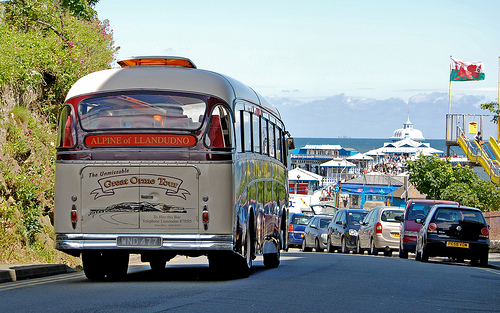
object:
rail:
[445, 113, 499, 144]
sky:
[94, 3, 498, 143]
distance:
[3, 4, 499, 166]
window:
[78, 95, 207, 130]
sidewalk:
[484, 237, 500, 270]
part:
[480, 248, 489, 267]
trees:
[5, 4, 110, 70]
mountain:
[269, 92, 491, 145]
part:
[296, 98, 369, 135]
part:
[382, 210, 403, 223]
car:
[286, 213, 315, 253]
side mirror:
[394, 216, 401, 221]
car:
[415, 204, 490, 266]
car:
[301, 215, 334, 253]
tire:
[209, 215, 253, 278]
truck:
[394, 199, 460, 259]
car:
[356, 206, 407, 255]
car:
[326, 209, 372, 253]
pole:
[447, 54, 453, 141]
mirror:
[287, 138, 295, 150]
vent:
[114, 55, 197, 70]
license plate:
[446, 241, 469, 248]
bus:
[51, 55, 296, 282]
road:
[0, 236, 499, 308]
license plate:
[119, 236, 160, 246]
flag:
[450, 56, 485, 81]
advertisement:
[83, 165, 199, 229]